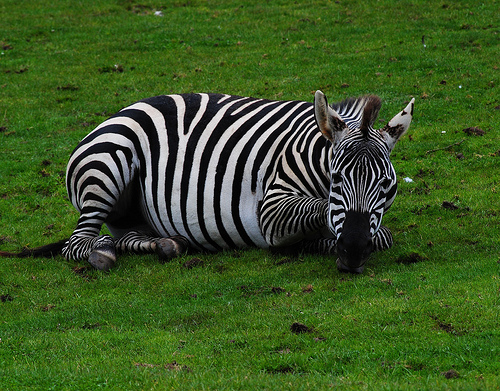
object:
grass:
[62, 20, 442, 72]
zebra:
[0, 90, 416, 275]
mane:
[332, 87, 383, 138]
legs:
[61, 190, 120, 258]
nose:
[338, 217, 373, 255]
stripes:
[120, 118, 285, 202]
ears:
[313, 89, 417, 144]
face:
[328, 141, 398, 268]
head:
[324, 121, 398, 268]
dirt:
[215, 315, 389, 346]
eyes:
[330, 171, 394, 189]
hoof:
[155, 238, 177, 261]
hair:
[18, 245, 53, 255]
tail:
[1, 236, 71, 258]